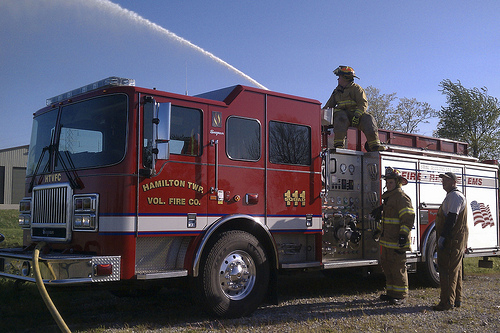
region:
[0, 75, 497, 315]
a large fire truck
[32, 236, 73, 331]
thick fire hose running over truck's bumper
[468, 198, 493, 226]
waving American flag decal on side of truck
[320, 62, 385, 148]
firefighter seated on top of truck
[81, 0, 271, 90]
long stream of water in the distance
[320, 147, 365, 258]
controls on side of truck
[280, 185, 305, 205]
gold colored numbers on fire truck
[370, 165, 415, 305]
man dressed in fire hat and outfit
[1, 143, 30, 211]
section of metal building in distance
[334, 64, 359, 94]
fire fighter is looking to his right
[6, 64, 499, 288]
the fire truck is red and white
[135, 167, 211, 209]
the state is hamilton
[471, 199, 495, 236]
ameriacn flag is on the firetruck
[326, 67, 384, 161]
the guy is on top of the fire truck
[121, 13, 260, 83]
water is spraying in the air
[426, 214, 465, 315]
his pants are black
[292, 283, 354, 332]
shadow is on the ground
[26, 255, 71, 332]
the hose pipe is yellow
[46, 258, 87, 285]
the surface is shiny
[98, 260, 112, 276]
the light is red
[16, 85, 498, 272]
the truck of fired department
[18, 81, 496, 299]
the truck is red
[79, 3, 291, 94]
water coming out of the truck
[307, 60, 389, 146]
the firefighter on the truck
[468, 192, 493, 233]
the flag on the truck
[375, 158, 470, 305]
firefighters beside the truck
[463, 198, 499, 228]
the american flag on the truck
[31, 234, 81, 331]
hose connected to the truck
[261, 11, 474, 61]
the sky is blue and clear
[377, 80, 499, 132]
trees behind the truck